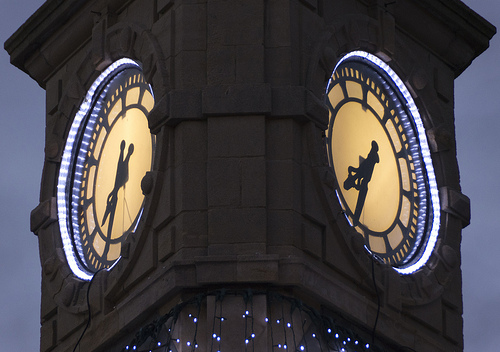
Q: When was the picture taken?
A: At night.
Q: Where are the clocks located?
A: At the top of a tower.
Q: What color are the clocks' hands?
A: Black.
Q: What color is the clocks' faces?
A: Yellow.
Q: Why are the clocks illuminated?
A: It's dark outside.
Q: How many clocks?
A: 2.